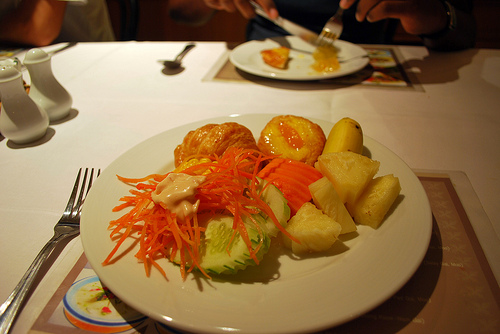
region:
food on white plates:
[76, 28, 437, 324]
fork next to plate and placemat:
[10, 160, 115, 327]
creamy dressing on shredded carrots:
[126, 165, 198, 250]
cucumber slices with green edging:
[192, 181, 279, 272]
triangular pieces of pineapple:
[302, 141, 393, 246]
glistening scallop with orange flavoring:
[255, 110, 320, 160]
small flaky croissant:
[170, 116, 255, 156]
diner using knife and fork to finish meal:
[220, 0, 407, 80]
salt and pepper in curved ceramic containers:
[0, 40, 75, 145]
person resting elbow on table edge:
[5, 2, 111, 48]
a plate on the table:
[51, 89, 446, 326]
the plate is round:
[69, 91, 439, 321]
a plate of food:
[63, 77, 455, 325]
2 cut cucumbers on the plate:
[190, 167, 295, 262]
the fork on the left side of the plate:
[8, 142, 96, 313]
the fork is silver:
[9, 157, 86, 332]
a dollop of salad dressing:
[137, 163, 218, 221]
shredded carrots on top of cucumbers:
[100, 156, 260, 223]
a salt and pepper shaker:
[0, 42, 89, 154]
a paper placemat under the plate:
[420, 135, 480, 317]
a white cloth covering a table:
[0, 40, 497, 331]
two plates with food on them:
[75, 31, 430, 328]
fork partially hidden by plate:
[0, 160, 101, 330]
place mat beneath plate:
[26, 165, 497, 331]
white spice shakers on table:
[0, 45, 74, 147]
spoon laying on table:
[156, 41, 196, 76]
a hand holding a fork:
[316, 1, 446, 46]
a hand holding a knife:
[208, 1, 333, 51]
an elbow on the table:
[3, 10, 63, 46]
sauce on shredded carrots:
[151, 171, 203, 217]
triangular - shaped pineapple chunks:
[291, 154, 391, 245]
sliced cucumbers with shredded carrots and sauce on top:
[110, 151, 279, 271]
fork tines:
[63, 165, 100, 232]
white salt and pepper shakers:
[2, 46, 76, 145]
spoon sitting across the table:
[157, 40, 194, 71]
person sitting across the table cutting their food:
[225, 0, 442, 82]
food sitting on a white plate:
[82, 110, 437, 330]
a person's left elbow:
[8, 2, 65, 46]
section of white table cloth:
[90, 73, 167, 120]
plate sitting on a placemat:
[30, 108, 495, 329]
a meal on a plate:
[55, 95, 472, 332]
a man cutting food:
[186, 0, 474, 87]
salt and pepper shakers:
[0, 37, 82, 159]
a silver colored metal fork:
[3, 160, 108, 328]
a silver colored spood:
[154, 40, 197, 82]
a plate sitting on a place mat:
[0, 141, 497, 330]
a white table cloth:
[8, 33, 495, 218]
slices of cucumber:
[166, 203, 270, 278]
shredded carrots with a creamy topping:
[110, 163, 270, 215]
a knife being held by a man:
[202, 0, 335, 55]